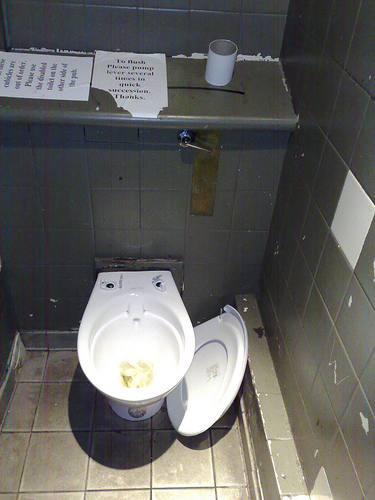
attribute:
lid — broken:
[102, 278, 166, 290]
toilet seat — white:
[165, 302, 246, 445]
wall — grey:
[75, 142, 161, 222]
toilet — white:
[69, 268, 199, 426]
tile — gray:
[85, 142, 142, 198]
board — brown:
[183, 130, 223, 218]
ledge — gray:
[249, 285, 279, 495]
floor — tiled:
[4, 418, 69, 487]